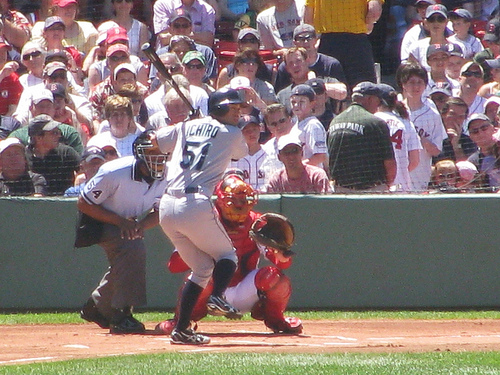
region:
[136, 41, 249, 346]
Baseball player ready to swing his bat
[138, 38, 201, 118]
Dark baseball bat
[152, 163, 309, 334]
Catcher in red padding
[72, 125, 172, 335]
Umpire leaning behind batter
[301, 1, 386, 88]
Person wearing a yellow shirt and navy shorts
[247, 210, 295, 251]
Leather baseball mitt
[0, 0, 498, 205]
Spectators watching a baseball game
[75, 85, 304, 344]
Three men playing baseball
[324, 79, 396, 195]
Old man facing away from the baseball game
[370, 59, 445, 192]
Two fans in baseball jerseys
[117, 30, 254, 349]
the man is batting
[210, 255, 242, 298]
the sock is long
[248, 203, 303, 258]
the mit is brown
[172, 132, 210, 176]
the number is black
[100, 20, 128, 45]
the cap is red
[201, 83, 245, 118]
the helmet is black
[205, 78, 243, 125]
the helmet is shiney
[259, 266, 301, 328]
the shin guards are red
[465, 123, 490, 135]
the man is wearing sunglasses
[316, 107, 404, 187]
the shirt is green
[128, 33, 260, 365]
Ichiro Suzuki batting as a member of the Seattle Mariners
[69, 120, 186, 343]
Home plate umpire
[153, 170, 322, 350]
The Red Sox' catcher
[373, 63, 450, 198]
A Boston fan standing up to get a better view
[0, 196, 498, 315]
Backstop behind home plate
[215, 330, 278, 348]
Home plate, seen at a sharp angle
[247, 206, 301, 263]
The catcher's mitt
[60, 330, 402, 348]
The batter's box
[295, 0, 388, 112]
A food or beer vendor in a yellow shirt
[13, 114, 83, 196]
A fan looking at somebody else in the crowd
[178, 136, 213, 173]
number on the back of a baseball jersey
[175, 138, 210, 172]
the baseball player's number on his jersey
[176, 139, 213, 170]
the number 51 on the back of a baseball jersey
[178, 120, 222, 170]
the baseball player's name and number on the back of his jersey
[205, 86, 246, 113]
black helmet on the baseball player's head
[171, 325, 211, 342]
baseball cleats on the player's foot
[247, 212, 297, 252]
brown baseball mitt on the catchers hand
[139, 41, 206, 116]
black baseball bat in the player's hands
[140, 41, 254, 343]
baseball player preparing to swing his bat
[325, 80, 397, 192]
man in a green shirt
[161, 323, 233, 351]
black and white sneakers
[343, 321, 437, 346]
red clay dirt on the field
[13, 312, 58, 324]
green grass on the field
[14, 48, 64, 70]
sun glasses on man's face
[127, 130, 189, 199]
mask on umpire's face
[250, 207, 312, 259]
black and red baseball gloves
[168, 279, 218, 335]
long black socks on man's feet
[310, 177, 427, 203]
edge of green wall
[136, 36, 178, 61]
tip of long black baseball bat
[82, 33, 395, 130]
spectators in the stands